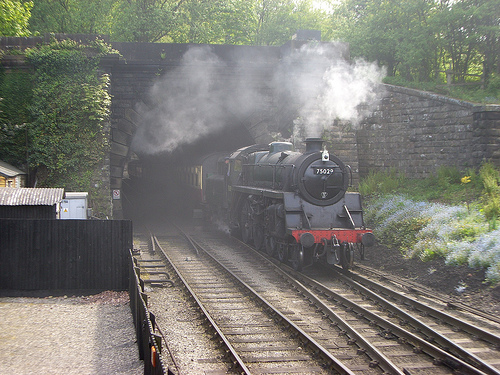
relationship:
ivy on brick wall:
[0, 34, 130, 175] [0, 33, 113, 218]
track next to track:
[138, 222, 498, 375] [228, 237, 498, 374]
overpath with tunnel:
[0, 29, 498, 196] [118, 87, 265, 240]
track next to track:
[138, 222, 337, 374] [309, 268, 499, 355]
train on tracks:
[178, 139, 374, 271] [203, 215, 499, 371]